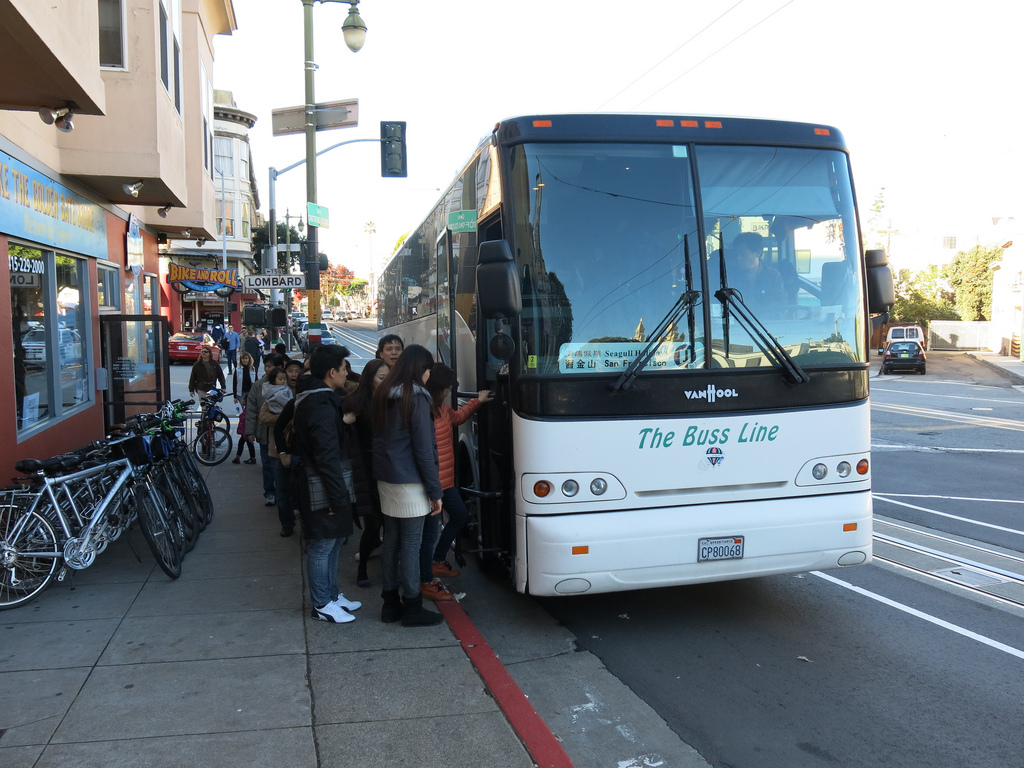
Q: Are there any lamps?
A: Yes, there is a lamp.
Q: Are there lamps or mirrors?
A: Yes, there is a lamp.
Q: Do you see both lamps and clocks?
A: No, there is a lamp but no clocks.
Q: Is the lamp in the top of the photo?
A: Yes, the lamp is in the top of the image.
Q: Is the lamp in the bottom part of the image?
A: No, the lamp is in the top of the image.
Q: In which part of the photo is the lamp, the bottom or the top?
A: The lamp is in the top of the image.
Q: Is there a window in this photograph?
A: Yes, there is a window.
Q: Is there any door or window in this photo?
A: Yes, there is a window.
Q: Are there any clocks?
A: No, there are no clocks.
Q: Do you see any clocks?
A: No, there are no clocks.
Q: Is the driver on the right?
A: Yes, the driver is on the right of the image.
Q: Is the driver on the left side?
A: No, the driver is on the right of the image.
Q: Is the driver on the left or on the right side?
A: The driver is on the right of the image.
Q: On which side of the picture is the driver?
A: The driver is on the right of the image.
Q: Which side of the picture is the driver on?
A: The driver is on the right of the image.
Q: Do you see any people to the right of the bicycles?
A: Yes, there is a person to the right of the bicycles.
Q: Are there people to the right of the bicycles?
A: Yes, there is a person to the right of the bicycles.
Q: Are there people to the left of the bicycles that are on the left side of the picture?
A: No, the person is to the right of the bicycles.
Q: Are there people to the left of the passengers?
A: Yes, there is a person to the left of the passengers.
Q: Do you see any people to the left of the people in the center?
A: Yes, there is a person to the left of the passengers.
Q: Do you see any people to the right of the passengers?
A: No, the person is to the left of the passengers.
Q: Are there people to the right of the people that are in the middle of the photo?
A: No, the person is to the left of the passengers.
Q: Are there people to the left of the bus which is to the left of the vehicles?
A: Yes, there is a person to the left of the bus.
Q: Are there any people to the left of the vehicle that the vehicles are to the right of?
A: Yes, there is a person to the left of the bus.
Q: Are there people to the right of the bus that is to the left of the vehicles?
A: No, the person is to the left of the bus.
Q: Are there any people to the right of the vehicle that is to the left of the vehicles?
A: No, the person is to the left of the bus.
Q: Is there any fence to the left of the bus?
A: No, there is a person to the left of the bus.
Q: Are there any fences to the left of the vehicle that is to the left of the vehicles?
A: No, there is a person to the left of the bus.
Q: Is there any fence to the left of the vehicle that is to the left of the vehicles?
A: No, there is a person to the left of the bus.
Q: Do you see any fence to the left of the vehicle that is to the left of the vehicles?
A: No, there is a person to the left of the bus.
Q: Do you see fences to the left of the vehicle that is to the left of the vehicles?
A: No, there is a person to the left of the bus.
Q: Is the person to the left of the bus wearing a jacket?
A: Yes, the person is wearing a jacket.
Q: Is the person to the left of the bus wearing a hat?
A: No, the person is wearing a jacket.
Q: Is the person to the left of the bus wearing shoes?
A: Yes, the person is wearing shoes.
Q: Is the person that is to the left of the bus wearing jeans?
A: No, the person is wearing shoes.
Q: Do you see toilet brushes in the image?
A: No, there are no toilet brushes.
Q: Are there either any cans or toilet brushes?
A: No, there are no toilet brushes or cans.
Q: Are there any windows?
A: Yes, there is a window.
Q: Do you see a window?
A: Yes, there is a window.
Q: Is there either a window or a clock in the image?
A: Yes, there is a window.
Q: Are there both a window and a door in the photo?
A: Yes, there are both a window and a door.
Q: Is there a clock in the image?
A: No, there are no clocks.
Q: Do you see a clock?
A: No, there are no clocks.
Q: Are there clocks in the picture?
A: No, there are no clocks.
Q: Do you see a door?
A: Yes, there are doors.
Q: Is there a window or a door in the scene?
A: Yes, there are doors.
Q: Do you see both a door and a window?
A: Yes, there are both a door and a window.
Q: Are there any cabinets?
A: No, there are no cabinets.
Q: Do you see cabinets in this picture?
A: No, there are no cabinets.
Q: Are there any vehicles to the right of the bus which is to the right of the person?
A: Yes, there are vehicles to the right of the bus.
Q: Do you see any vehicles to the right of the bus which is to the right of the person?
A: Yes, there are vehicles to the right of the bus.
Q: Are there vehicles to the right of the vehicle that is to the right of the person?
A: Yes, there are vehicles to the right of the bus.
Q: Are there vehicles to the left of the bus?
A: No, the vehicles are to the right of the bus.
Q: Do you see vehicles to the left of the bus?
A: No, the vehicles are to the right of the bus.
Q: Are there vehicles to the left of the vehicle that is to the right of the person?
A: No, the vehicles are to the right of the bus.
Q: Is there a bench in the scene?
A: No, there are no benches.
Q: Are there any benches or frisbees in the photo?
A: No, there are no benches or frisbees.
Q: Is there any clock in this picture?
A: No, there are no clocks.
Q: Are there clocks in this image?
A: No, there are no clocks.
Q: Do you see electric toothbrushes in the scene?
A: No, there are no electric toothbrushes.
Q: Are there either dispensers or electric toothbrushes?
A: No, there are no electric toothbrushes or dispensers.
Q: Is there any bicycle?
A: Yes, there are bicycles.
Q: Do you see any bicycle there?
A: Yes, there are bicycles.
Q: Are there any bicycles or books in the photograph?
A: Yes, there are bicycles.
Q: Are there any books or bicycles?
A: Yes, there are bicycles.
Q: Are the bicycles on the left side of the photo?
A: Yes, the bicycles are on the left of the image.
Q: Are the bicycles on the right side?
A: No, the bicycles are on the left of the image.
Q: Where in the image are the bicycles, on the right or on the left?
A: The bicycles are on the left of the image.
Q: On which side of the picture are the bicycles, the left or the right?
A: The bicycles are on the left of the image.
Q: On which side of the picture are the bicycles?
A: The bicycles are on the left of the image.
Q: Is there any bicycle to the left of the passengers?
A: Yes, there are bicycles to the left of the passengers.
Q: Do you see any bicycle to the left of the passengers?
A: Yes, there are bicycles to the left of the passengers.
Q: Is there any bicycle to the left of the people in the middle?
A: Yes, there are bicycles to the left of the passengers.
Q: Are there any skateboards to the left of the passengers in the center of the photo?
A: No, there are bicycles to the left of the passengers.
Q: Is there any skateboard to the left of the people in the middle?
A: No, there are bicycles to the left of the passengers.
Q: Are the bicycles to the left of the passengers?
A: Yes, the bicycles are to the left of the passengers.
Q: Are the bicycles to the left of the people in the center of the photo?
A: Yes, the bicycles are to the left of the passengers.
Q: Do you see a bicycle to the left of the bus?
A: Yes, there are bicycles to the left of the bus.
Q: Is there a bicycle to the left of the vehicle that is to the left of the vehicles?
A: Yes, there are bicycles to the left of the bus.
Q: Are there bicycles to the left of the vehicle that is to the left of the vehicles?
A: Yes, there are bicycles to the left of the bus.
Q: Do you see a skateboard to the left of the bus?
A: No, there are bicycles to the left of the bus.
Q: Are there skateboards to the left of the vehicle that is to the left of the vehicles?
A: No, there are bicycles to the left of the bus.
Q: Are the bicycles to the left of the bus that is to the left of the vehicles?
A: Yes, the bicycles are to the left of the bus.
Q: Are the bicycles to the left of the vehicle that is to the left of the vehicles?
A: Yes, the bicycles are to the left of the bus.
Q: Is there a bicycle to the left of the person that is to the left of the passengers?
A: Yes, there are bicycles to the left of the person.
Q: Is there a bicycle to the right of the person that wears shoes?
A: No, the bicycles are to the left of the person.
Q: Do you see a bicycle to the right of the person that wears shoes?
A: No, the bicycles are to the left of the person.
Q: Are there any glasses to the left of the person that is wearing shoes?
A: No, there are bicycles to the left of the person.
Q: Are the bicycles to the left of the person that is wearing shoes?
A: Yes, the bicycles are to the left of the person.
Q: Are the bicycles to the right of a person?
A: No, the bicycles are to the left of a person.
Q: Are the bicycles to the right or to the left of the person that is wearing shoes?
A: The bicycles are to the left of the person.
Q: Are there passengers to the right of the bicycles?
A: Yes, there are passengers to the right of the bicycles.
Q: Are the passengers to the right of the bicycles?
A: Yes, the passengers are to the right of the bicycles.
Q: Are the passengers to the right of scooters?
A: No, the passengers are to the right of the bicycles.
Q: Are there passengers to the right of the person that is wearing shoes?
A: Yes, there are passengers to the right of the person.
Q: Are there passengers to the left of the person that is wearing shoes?
A: No, the passengers are to the right of the person.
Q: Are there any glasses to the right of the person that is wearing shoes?
A: No, there are passengers to the right of the person.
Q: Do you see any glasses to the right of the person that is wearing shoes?
A: No, there are passengers to the right of the person.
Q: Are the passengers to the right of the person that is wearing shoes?
A: Yes, the passengers are to the right of the person.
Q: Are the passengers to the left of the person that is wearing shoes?
A: No, the passengers are to the right of the person.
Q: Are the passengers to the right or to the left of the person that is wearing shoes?
A: The passengers are to the right of the person.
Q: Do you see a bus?
A: Yes, there is a bus.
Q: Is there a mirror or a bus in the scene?
A: Yes, there is a bus.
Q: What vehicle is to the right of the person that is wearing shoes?
A: The vehicle is a bus.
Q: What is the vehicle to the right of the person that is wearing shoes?
A: The vehicle is a bus.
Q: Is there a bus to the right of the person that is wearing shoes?
A: Yes, there is a bus to the right of the person.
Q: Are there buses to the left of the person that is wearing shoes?
A: No, the bus is to the right of the person.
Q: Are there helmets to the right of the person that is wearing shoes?
A: No, there is a bus to the right of the person.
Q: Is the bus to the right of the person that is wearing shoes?
A: Yes, the bus is to the right of the person.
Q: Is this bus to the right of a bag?
A: No, the bus is to the right of the person.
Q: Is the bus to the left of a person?
A: No, the bus is to the right of a person.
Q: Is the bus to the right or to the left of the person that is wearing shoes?
A: The bus is to the right of the person.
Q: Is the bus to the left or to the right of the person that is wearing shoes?
A: The bus is to the right of the person.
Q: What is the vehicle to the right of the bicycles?
A: The vehicle is a bus.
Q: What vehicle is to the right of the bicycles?
A: The vehicle is a bus.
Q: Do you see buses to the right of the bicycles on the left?
A: Yes, there is a bus to the right of the bicycles.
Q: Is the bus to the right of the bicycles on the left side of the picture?
A: Yes, the bus is to the right of the bicycles.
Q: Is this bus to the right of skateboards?
A: No, the bus is to the right of the bicycles.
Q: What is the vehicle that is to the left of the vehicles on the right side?
A: The vehicle is a bus.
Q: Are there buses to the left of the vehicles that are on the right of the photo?
A: Yes, there is a bus to the left of the vehicles.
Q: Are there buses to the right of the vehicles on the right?
A: No, the bus is to the left of the vehicles.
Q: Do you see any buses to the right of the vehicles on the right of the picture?
A: No, the bus is to the left of the vehicles.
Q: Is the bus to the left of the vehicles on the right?
A: Yes, the bus is to the left of the vehicles.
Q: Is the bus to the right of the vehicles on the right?
A: No, the bus is to the left of the vehicles.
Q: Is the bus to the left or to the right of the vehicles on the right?
A: The bus is to the left of the vehicles.